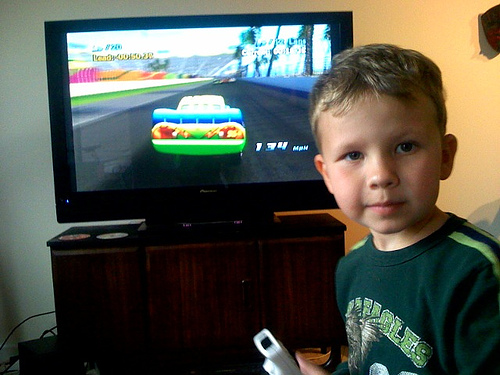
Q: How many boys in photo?
A: One.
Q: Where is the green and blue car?
A: Television.